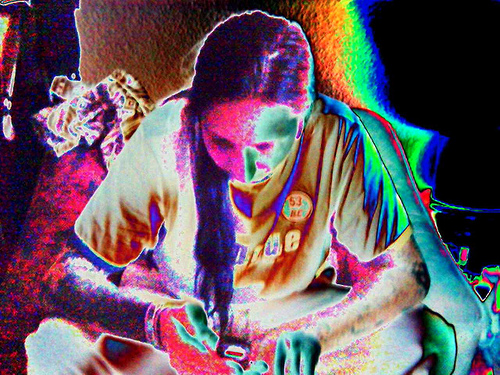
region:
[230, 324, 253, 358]
This person is using a cell phone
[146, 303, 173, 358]
This person is wearing a wrist watch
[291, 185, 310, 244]
This person has the number 53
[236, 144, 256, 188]
This person has a large nose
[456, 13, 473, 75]
This color is a dark black color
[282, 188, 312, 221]
the number 53 inside a circle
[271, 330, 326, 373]
green colored fingers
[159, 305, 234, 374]
a red colored hand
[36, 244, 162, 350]
a purple arm with blue and pink spots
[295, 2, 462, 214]
blue, green, yellow, and orange colors in the background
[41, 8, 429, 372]
woman with long dark hair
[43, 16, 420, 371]
woman wearing a white shirt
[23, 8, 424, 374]
the woman is sitting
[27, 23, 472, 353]
a person sitting in a chair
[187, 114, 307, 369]
she is looking at something with her hand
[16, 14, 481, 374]
this image color has been distorted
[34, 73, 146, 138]
items on the back of the chair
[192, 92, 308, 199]
hteir is pink spot on the girl's face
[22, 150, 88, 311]
an item that has been turned pink and blue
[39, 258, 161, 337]
the color on her arm has been altered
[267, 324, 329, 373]
she has light blue hands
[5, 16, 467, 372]
this is a painting of a person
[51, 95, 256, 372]
the hand of a person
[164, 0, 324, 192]
the head of a person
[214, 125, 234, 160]
the eye of a person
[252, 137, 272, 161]
the eye of a person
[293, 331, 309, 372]
the finger of a person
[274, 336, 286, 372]
the finger of a person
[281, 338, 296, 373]
the finger of a person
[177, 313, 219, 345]
the finger of a person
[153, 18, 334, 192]
head of a person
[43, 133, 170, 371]
arm of a person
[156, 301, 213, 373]
hand of a person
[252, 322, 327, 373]
hand of a person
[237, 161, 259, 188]
nose of a person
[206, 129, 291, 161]
eye of a person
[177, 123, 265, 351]
hair of a person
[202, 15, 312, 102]
hair of a person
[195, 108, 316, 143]
forehead of a person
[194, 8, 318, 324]
hair worn long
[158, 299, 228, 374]
hand belongs to human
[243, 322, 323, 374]
hand belongs to human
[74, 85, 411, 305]
shirt worn by human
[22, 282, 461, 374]
pants worn by human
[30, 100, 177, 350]
arm belongs to human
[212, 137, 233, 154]
eye belongs to human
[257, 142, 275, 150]
eye belongs to human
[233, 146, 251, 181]
nose belongs to human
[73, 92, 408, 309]
shirt worn by human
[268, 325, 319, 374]
hand belongs to human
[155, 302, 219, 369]
hand belongs to human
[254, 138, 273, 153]
eye belongs to human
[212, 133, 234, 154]
eye belongs to human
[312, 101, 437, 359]
arm belongs to human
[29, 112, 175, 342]
arm belongs to human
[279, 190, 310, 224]
sticker attached to shirt